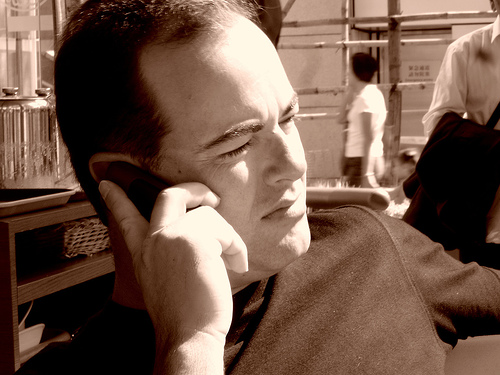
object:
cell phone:
[101, 161, 169, 222]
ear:
[88, 152, 142, 184]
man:
[11, 0, 498, 375]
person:
[340, 52, 389, 187]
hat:
[352, 53, 380, 74]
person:
[403, 14, 500, 271]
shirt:
[420, 11, 500, 244]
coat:
[402, 111, 500, 252]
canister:
[0, 87, 61, 187]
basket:
[30, 218, 111, 261]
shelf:
[0, 188, 116, 374]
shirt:
[345, 84, 389, 158]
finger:
[98, 180, 149, 251]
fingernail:
[100, 182, 111, 199]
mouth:
[260, 191, 305, 221]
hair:
[51, 0, 273, 227]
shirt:
[11, 205, 500, 374]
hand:
[98, 179, 251, 336]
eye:
[217, 135, 254, 157]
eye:
[279, 111, 300, 124]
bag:
[485, 101, 499, 128]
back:
[1, 309, 21, 374]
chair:
[13, 341, 71, 374]